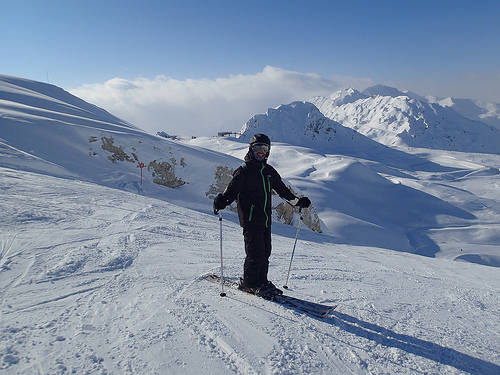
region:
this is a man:
[214, 117, 313, 288]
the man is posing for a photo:
[222, 129, 296, 273]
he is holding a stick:
[281, 216, 306, 282]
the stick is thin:
[278, 229, 305, 280]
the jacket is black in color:
[238, 164, 271, 225]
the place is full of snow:
[71, 278, 212, 370]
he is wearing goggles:
[252, 142, 270, 150]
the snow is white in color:
[41, 264, 168, 372]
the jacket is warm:
[240, 165, 274, 227]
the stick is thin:
[206, 222, 233, 279]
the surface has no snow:
[143, 148, 188, 188]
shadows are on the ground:
[323, 305, 452, 373]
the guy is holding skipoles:
[207, 120, 343, 333]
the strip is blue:
[253, 165, 273, 235]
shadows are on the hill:
[338, 132, 453, 235]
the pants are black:
[237, 235, 288, 286]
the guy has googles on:
[212, 136, 319, 311]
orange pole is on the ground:
[130, 155, 161, 196]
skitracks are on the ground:
[47, 227, 183, 350]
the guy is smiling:
[212, 126, 350, 333]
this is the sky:
[169, 10, 271, 42]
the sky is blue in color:
[281, 3, 351, 53]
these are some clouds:
[122, 75, 233, 122]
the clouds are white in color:
[158, 81, 222, 119]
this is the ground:
[62, 218, 149, 315]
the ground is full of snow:
[83, 252, 179, 367]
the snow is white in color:
[72, 257, 158, 332]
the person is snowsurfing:
[193, 118, 328, 320]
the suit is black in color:
[247, 226, 266, 253]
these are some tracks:
[22, 224, 157, 306]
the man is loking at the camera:
[212, 139, 324, 314]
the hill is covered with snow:
[348, 96, 455, 143]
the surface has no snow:
[157, 163, 178, 190]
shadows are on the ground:
[335, 292, 470, 372]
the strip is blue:
[257, 170, 285, 236]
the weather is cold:
[3, 93, 496, 372]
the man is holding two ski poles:
[195, 143, 363, 338]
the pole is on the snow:
[133, 158, 155, 190]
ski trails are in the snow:
[43, 226, 199, 349]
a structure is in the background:
[213, 126, 246, 145]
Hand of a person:
[215, 165, 249, 220]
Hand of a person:
[267, 163, 322, 208]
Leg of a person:
[235, 214, 265, 299]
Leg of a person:
[259, 221, 284, 293]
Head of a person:
[248, 125, 275, 162]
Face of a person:
[254, 140, 271, 160]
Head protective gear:
[248, 128, 271, 162]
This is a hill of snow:
[6, 77, 101, 122]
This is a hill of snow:
[241, 88, 333, 139]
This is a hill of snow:
[322, 73, 436, 132]